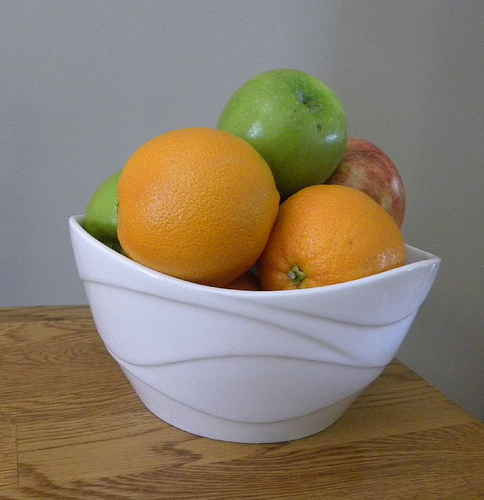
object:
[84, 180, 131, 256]
fruit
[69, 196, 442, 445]
bowl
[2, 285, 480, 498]
table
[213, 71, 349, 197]
apple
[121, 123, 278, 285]
orange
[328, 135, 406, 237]
apple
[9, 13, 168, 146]
wall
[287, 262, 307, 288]
stem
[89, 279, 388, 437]
design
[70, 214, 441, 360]
curved edge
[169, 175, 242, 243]
texture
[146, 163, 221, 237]
peel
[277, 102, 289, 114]
specks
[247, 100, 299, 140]
skin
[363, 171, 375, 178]
undertones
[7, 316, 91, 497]
grain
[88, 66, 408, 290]
mixed fruit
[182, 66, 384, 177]
top